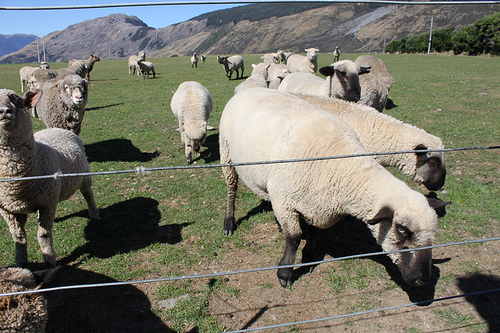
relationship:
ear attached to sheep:
[411, 139, 426, 159] [251, 108, 442, 238]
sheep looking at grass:
[251, 108, 442, 238] [160, 174, 188, 191]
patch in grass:
[193, 264, 247, 292] [160, 174, 188, 191]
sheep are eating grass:
[251, 108, 442, 238] [160, 174, 188, 191]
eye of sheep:
[399, 238, 411, 251] [251, 108, 442, 238]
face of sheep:
[385, 214, 428, 290] [251, 108, 442, 238]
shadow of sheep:
[82, 185, 167, 248] [251, 108, 442, 238]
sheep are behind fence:
[251, 108, 442, 238] [113, 152, 172, 174]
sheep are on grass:
[251, 108, 442, 238] [160, 174, 188, 191]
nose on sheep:
[442, 187, 443, 188] [251, 108, 442, 238]